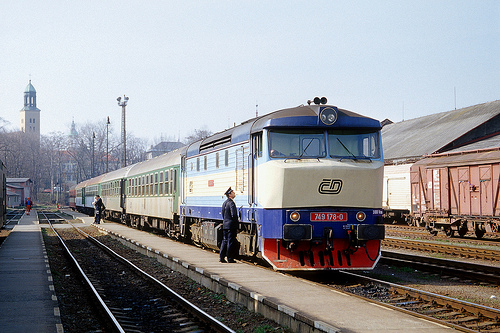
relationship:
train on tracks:
[55, 94, 387, 279] [292, 267, 499, 332]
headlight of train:
[287, 207, 302, 223] [229, 112, 374, 299]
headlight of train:
[351, 204, 372, 222] [229, 112, 374, 299]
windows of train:
[266, 127, 380, 159] [118, 110, 385, 277]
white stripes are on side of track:
[248, 292, 263, 302] [40, 200, 313, 331]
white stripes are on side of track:
[169, 256, 180, 264] [40, 200, 313, 331]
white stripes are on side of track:
[48, 284, 55, 290] [40, 200, 313, 331]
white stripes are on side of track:
[116, 234, 121, 239] [40, 200, 313, 331]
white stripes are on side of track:
[275, 304, 297, 316] [40, 200, 313, 331]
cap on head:
[222, 185, 234, 195] [219, 181, 239, 201]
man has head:
[218, 185, 239, 263] [219, 181, 239, 201]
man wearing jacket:
[218, 185, 239, 263] [220, 198, 240, 228]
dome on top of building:
[12, 77, 37, 116] [0, 82, 130, 204]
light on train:
[318, 102, 341, 124] [55, 94, 387, 279]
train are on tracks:
[55, 94, 387, 279] [390, 242, 497, 326]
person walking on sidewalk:
[11, 184, 47, 218] [5, 207, 48, 331]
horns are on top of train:
[306, 96, 328, 105] [55, 94, 387, 279]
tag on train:
[309, 211, 348, 222] [55, 94, 387, 279]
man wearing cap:
[218, 185, 239, 263] [222, 185, 234, 195]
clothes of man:
[220, 197, 238, 253] [215, 186, 242, 271]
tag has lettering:
[309, 209, 351, 224] [315, 213, 344, 220]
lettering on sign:
[310, 208, 346, 225] [277, 199, 377, 235]